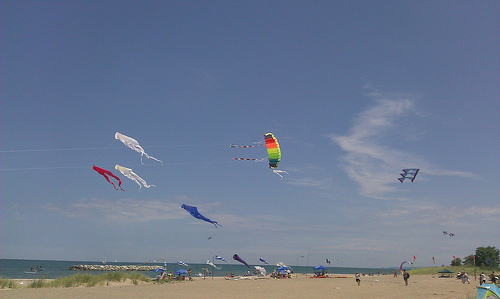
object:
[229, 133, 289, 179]
kite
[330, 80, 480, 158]
cloud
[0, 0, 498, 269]
sky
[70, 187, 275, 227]
cloud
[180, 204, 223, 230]
kite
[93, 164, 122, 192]
kite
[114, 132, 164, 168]
kite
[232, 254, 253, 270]
wind sock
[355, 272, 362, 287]
person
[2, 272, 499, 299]
beach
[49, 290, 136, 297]
sand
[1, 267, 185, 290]
grass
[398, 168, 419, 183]
kite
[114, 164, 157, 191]
kite